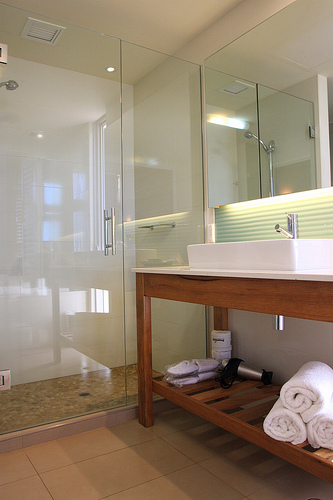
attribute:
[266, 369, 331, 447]
towels — fluffy, white, rolled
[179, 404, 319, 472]
shelf — wooden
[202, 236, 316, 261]
sink — modern, supported, white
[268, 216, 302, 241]
faucet — modern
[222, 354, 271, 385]
blow dryer — silver, black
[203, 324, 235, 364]
toilet paper — stacked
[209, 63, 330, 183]
mirror — large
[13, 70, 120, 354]
shower — stand up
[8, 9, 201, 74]
ceiling — white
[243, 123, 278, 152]
shower head — silver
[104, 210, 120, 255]
handle — silver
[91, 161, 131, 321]
door — glass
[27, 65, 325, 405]
bathroom — white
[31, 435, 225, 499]
ground — tiled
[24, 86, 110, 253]
wall — white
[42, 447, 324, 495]
floor — tiled, beige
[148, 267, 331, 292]
table — wooden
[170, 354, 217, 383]
slippers — white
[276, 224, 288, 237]
tap — metallic